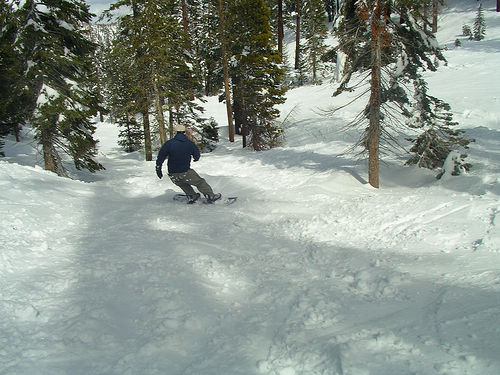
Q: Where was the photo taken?
A: Mountains.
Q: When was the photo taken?
A: Winter.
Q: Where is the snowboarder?
A: In forest.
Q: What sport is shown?
A: Snowboarding.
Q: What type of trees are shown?
A: Pine.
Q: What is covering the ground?
A: Snow.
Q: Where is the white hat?
A: On snowboarder.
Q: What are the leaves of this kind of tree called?
A: Needles.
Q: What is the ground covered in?
A: Snow.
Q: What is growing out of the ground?
A: Pine trees.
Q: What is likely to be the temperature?
A: Very cold.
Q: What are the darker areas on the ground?
A: The trees shadows.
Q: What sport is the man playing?
A: Snowboarding.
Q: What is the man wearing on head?
A: A gray hat.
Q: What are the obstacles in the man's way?
A: There are trees.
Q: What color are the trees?
A: Green.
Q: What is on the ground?
A: Snow.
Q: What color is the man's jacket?
A: Blue.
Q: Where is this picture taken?
A: The ski slope.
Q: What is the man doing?
A: Skiing.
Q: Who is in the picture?
A: A man.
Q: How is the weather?
A: Clear.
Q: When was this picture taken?
A: Daytime.